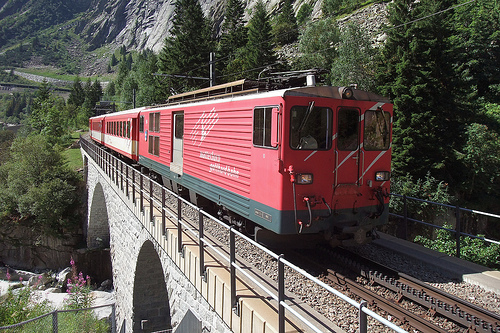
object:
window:
[253, 106, 279, 148]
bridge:
[78, 136, 499, 332]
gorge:
[3, 226, 125, 321]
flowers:
[66, 257, 89, 295]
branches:
[71, 294, 88, 309]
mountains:
[92, 0, 328, 60]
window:
[337, 109, 359, 151]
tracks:
[303, 243, 500, 333]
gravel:
[288, 277, 373, 332]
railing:
[76, 134, 404, 333]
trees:
[376, 0, 499, 207]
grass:
[57, 132, 81, 171]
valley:
[2, 5, 91, 181]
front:
[281, 85, 394, 244]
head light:
[296, 173, 314, 185]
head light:
[375, 171, 391, 182]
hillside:
[81, 0, 171, 37]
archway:
[83, 181, 113, 292]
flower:
[4, 271, 48, 295]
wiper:
[296, 100, 316, 149]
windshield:
[290, 106, 334, 151]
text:
[197, 150, 240, 179]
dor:
[336, 106, 361, 184]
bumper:
[329, 223, 378, 247]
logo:
[189, 107, 220, 149]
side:
[142, 95, 282, 232]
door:
[171, 110, 184, 174]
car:
[89, 75, 393, 245]